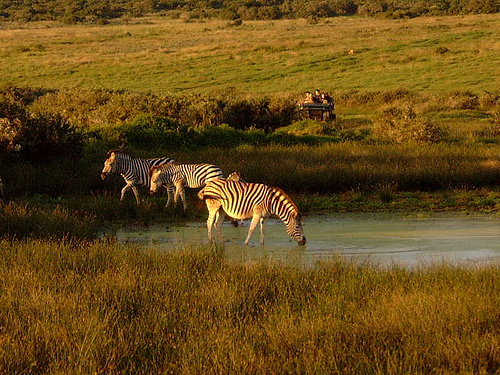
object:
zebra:
[196, 178, 307, 253]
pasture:
[1, 207, 498, 373]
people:
[305, 89, 312, 106]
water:
[102, 214, 499, 265]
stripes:
[211, 179, 286, 218]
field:
[4, 1, 500, 145]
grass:
[6, 31, 497, 86]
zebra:
[98, 151, 170, 197]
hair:
[275, 187, 301, 218]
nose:
[296, 238, 307, 247]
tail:
[197, 187, 221, 202]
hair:
[207, 196, 223, 202]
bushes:
[6, 113, 84, 166]